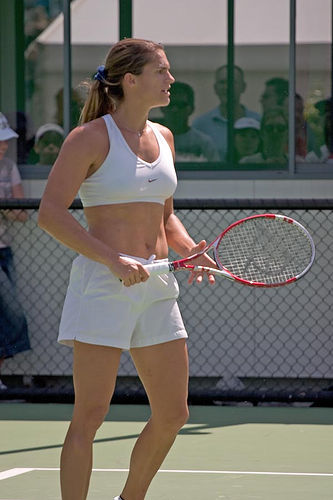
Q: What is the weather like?
A: Clear and sunny.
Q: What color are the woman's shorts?
A: White.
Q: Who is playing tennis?
A: The woman wearing white.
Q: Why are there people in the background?
A: They are watching the tennis match.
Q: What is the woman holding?
A: A tennis racket.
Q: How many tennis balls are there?
A: Zero.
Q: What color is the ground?
A: Green with white stripes.